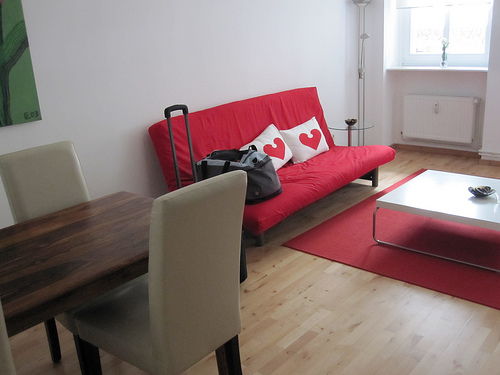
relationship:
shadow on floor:
[284, 206, 380, 238] [148, 139, 497, 374]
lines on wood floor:
[270, 281, 340, 311] [148, 139, 497, 374]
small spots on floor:
[240, 285, 284, 304] [148, 139, 497, 374]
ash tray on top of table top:
[473, 185, 499, 199] [373, 172, 498, 249]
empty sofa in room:
[162, 92, 404, 215] [3, 3, 499, 373]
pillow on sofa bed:
[287, 121, 329, 152] [162, 92, 404, 215]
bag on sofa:
[205, 150, 282, 191] [162, 92, 404, 215]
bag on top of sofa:
[205, 150, 282, 191] [162, 92, 404, 215]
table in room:
[4, 198, 231, 319] [3, 3, 499, 373]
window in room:
[391, 2, 485, 67] [3, 3, 499, 373]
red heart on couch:
[264, 140, 289, 160] [162, 92, 404, 215]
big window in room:
[391, 2, 485, 67] [3, 3, 499, 373]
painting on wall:
[2, 2, 43, 130] [6, 4, 355, 132]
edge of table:
[47, 287, 112, 295] [4, 198, 231, 319]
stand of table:
[372, 209, 499, 276] [373, 172, 498, 249]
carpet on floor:
[281, 167, 499, 311] [148, 139, 497, 374]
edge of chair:
[47, 287, 112, 295] [93, 212, 265, 370]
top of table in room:
[1, 212, 160, 292] [3, 3, 499, 373]